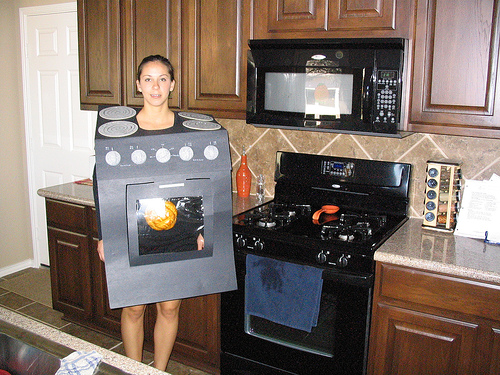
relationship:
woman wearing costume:
[89, 54, 233, 367] [94, 109, 233, 243]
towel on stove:
[240, 249, 327, 335] [220, 147, 412, 373]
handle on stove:
[316, 250, 327, 264] [220, 147, 412, 373]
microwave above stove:
[245, 38, 413, 136] [220, 147, 412, 373]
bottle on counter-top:
[235, 152, 251, 197] [37, 176, 499, 285]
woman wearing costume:
[91, 55, 232, 367] [94, 102, 238, 308]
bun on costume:
[144, 198, 179, 234] [87, 98, 244, 315]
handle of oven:
[214, 245, 376, 275] [217, 148, 410, 373]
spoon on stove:
[312, 204, 338, 220] [253, 195, 388, 253]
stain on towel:
[248, 256, 293, 304] [182, 232, 348, 365]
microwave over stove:
[236, 17, 413, 147] [220, 147, 412, 373]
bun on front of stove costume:
[144, 198, 179, 234] [87, 98, 244, 315]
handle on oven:
[314, 250, 353, 273] [221, 150, 411, 375]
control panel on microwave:
[370, 72, 400, 129] [245, 38, 413, 136]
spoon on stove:
[312, 204, 338, 220] [220, 147, 412, 373]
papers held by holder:
[450, 172, 499, 247] [478, 225, 484, 240]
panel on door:
[127, 186, 213, 249] [117, 166, 239, 287]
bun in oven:
[142, 196, 178, 233] [233, 201, 366, 373]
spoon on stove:
[312, 199, 340, 229] [241, 189, 400, 305]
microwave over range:
[245, 38, 413, 136] [235, 186, 392, 256]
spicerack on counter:
[417, 154, 461, 234] [373, 201, 483, 283]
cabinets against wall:
[80, 8, 492, 138] [74, 5, 474, 343]